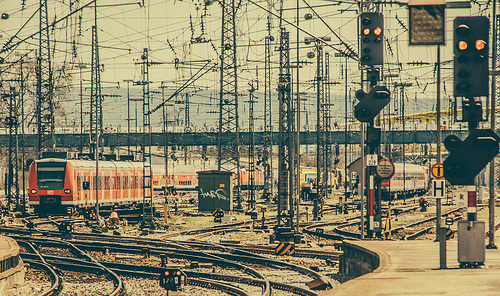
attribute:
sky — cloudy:
[1, 1, 499, 131]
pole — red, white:
[365, 177, 376, 240]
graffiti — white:
[199, 186, 229, 202]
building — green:
[197, 171, 230, 213]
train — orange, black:
[31, 146, 350, 207]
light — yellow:
[65, 189, 67, 194]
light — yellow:
[31, 190, 35, 193]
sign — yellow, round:
[430, 165, 444, 179]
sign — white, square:
[431, 179, 446, 199]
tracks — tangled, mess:
[4, 194, 497, 296]